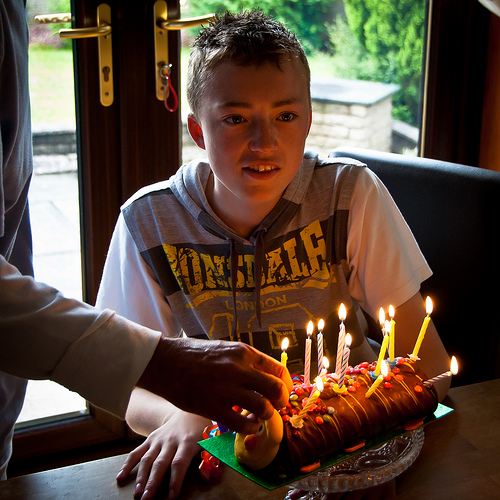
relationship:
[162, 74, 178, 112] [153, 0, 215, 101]
loop on handle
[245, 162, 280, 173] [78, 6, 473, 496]
teeth on boy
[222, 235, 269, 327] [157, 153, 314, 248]
strings on hood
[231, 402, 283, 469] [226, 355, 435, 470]
face on cake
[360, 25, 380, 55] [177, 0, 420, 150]
foilage in window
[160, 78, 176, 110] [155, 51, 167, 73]
key in door lock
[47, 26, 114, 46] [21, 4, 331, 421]
handle on door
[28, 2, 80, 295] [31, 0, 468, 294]
window in door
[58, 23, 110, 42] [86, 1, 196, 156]
handle on door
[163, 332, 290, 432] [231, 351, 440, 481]
hand touching cake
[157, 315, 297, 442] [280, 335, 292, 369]
hand placing candle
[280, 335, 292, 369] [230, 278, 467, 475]
candle on cake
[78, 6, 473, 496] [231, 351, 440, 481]
boy behind cake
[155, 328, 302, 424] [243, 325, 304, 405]
hand holding candle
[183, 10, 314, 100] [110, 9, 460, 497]
hair on boy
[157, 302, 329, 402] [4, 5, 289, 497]
hand on man